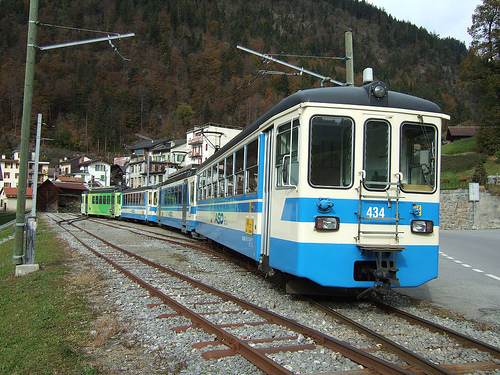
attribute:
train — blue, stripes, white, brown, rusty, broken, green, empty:
[154, 112, 439, 283]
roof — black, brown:
[197, 92, 420, 112]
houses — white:
[57, 101, 224, 188]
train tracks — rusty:
[110, 203, 267, 373]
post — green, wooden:
[13, 20, 45, 276]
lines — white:
[442, 246, 494, 278]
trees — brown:
[96, 70, 224, 111]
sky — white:
[398, 0, 461, 34]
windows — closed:
[154, 161, 264, 216]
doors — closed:
[156, 116, 306, 281]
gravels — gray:
[111, 244, 209, 281]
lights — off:
[284, 206, 448, 257]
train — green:
[63, 176, 143, 222]